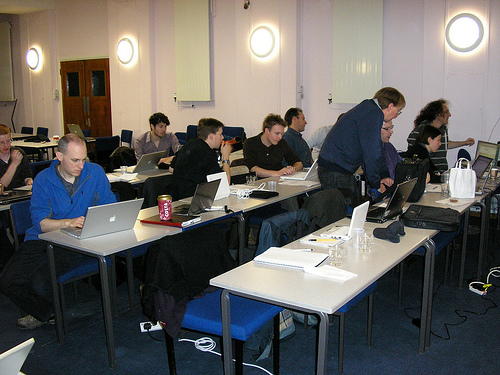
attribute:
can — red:
[157, 190, 180, 227]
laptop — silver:
[80, 189, 151, 237]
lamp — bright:
[445, 17, 492, 46]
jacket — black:
[309, 191, 348, 220]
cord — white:
[166, 328, 227, 359]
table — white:
[218, 232, 428, 291]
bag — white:
[449, 160, 478, 205]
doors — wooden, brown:
[59, 60, 121, 132]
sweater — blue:
[343, 94, 382, 190]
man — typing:
[51, 137, 109, 223]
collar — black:
[281, 227, 308, 237]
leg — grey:
[310, 310, 329, 373]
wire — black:
[145, 330, 170, 347]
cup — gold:
[490, 166, 497, 185]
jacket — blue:
[265, 211, 307, 249]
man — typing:
[268, 110, 294, 185]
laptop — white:
[296, 151, 321, 194]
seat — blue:
[202, 289, 259, 334]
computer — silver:
[121, 159, 168, 179]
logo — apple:
[107, 210, 120, 232]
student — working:
[290, 110, 314, 164]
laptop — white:
[211, 174, 235, 197]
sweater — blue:
[33, 158, 93, 229]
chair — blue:
[431, 235, 462, 270]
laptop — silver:
[193, 185, 215, 214]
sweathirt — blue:
[385, 145, 395, 173]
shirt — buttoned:
[247, 130, 285, 172]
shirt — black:
[416, 142, 427, 174]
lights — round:
[105, 32, 483, 65]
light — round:
[110, 26, 142, 74]